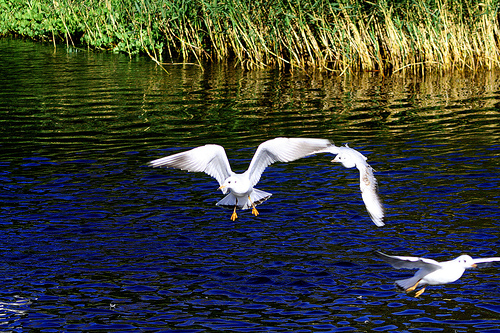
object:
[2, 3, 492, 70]
grass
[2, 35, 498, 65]
shore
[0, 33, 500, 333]
water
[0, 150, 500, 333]
dark spot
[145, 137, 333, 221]
bird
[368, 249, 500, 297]
bird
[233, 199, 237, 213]
leg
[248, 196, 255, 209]
leg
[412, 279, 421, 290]
leg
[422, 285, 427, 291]
leg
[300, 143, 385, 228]
bird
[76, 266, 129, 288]
dark spot